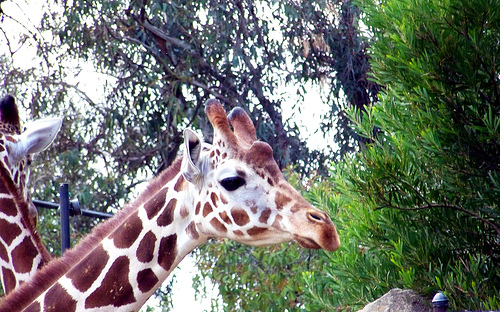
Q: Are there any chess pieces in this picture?
A: No, there are no chess pieces.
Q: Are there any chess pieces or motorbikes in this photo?
A: No, there are no chess pieces or motorbikes.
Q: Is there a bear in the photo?
A: No, there are no bears.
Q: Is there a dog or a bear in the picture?
A: No, there are no bears or dogs.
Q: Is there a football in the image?
A: No, there are no footballs.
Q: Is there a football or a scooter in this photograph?
A: No, there are no footballs or scooters.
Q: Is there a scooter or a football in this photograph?
A: No, there are no footballs or scooters.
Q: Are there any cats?
A: No, there are no cats.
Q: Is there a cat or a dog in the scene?
A: No, there are no cats or dogs.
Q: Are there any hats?
A: Yes, there is a hat.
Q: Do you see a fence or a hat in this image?
A: Yes, there is a hat.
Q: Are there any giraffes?
A: Yes, there is a giraffe.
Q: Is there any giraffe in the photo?
A: Yes, there is a giraffe.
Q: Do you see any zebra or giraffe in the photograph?
A: Yes, there is a giraffe.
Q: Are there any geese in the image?
A: No, there are no geese.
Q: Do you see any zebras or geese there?
A: No, there are no geese or zebras.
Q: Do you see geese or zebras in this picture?
A: No, there are no geese or zebras.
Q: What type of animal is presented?
A: The animal is a giraffe.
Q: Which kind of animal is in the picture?
A: The animal is a giraffe.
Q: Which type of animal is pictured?
A: The animal is a giraffe.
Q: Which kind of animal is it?
A: The animal is a giraffe.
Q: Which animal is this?
A: This is a giraffe.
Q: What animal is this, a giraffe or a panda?
A: This is a giraffe.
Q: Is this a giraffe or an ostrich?
A: This is a giraffe.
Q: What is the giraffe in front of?
A: The giraffe is in front of the trees.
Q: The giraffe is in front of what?
A: The giraffe is in front of the trees.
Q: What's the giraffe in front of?
A: The giraffe is in front of the trees.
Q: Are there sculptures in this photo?
A: No, there are no sculptures.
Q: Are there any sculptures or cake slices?
A: No, there are no sculptures or cake slices.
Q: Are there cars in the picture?
A: No, there are no cars.